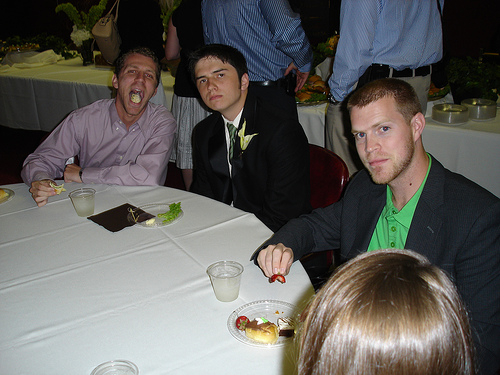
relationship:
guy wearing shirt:
[255, 76, 499, 373] [367, 156, 431, 250]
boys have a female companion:
[24, 48, 496, 347] [294, 246, 477, 373]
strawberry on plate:
[229, 306, 252, 342] [217, 280, 294, 355]